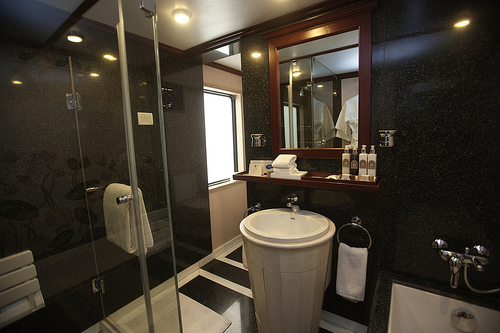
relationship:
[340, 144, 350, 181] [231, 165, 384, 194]
bottle sitting on shelf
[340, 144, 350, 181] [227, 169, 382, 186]
bottle sitting on shelf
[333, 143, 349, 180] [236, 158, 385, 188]
bottle sitting on shelf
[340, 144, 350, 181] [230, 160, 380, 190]
bottle sitting on shelf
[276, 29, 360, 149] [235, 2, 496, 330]
mirror hanging on wall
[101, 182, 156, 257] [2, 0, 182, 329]
towel hanging on door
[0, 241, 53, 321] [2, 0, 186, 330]
seat in shower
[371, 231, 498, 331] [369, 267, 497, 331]
faucet in bathtub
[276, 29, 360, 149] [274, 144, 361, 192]
mirror above sink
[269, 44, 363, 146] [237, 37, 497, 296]
mirror on wall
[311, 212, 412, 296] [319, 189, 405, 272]
towel in holder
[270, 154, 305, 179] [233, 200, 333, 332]
towels above sink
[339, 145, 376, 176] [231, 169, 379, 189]
toiletries on shelf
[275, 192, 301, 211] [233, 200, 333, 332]
faucet above sink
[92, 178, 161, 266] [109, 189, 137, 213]
towel on door handle